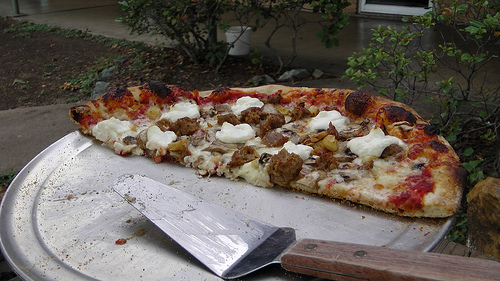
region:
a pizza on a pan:
[79, 52, 486, 259]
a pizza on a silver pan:
[29, 34, 496, 254]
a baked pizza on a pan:
[73, 57, 485, 275]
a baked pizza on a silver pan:
[14, 51, 483, 278]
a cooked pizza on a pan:
[44, 48, 413, 278]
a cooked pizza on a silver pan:
[87, 40, 446, 279]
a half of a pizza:
[54, 31, 406, 275]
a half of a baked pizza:
[55, 43, 389, 275]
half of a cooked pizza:
[73, 46, 462, 278]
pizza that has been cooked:
[75, 43, 499, 243]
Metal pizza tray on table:
[44, 147, 151, 274]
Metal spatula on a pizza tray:
[119, 151, 281, 263]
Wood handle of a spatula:
[293, 221, 462, 276]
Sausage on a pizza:
[269, 132, 309, 184]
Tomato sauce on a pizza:
[402, 148, 429, 229]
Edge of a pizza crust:
[423, 186, 447, 218]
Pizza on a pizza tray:
[87, 67, 464, 227]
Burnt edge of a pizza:
[341, 86, 421, 151]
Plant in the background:
[344, 43, 451, 103]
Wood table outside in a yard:
[7, 106, 47, 141]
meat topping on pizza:
[264, 149, 306, 186]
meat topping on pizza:
[257, 112, 284, 139]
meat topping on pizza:
[223, 146, 258, 171]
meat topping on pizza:
[260, 130, 289, 148]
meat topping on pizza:
[173, 117, 202, 139]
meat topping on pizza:
[166, 134, 190, 157]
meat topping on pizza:
[217, 108, 236, 127]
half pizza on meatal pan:
[0, 81, 459, 279]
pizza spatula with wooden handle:
[114, 173, 497, 279]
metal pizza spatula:
[112, 172, 497, 278]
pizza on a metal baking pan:
[81, 80, 370, 181]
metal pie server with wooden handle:
[96, 158, 322, 268]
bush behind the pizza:
[359, 18, 476, 145]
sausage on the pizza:
[266, 145, 302, 180]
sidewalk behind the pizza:
[14, 103, 69, 163]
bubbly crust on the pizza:
[63, 79, 183, 116]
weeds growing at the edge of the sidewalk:
[26, 12, 96, 47]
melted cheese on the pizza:
[357, 140, 381, 155]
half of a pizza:
[90, 45, 455, 230]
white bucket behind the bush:
[222, 26, 251, 60]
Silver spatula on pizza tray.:
[126, 172, 244, 278]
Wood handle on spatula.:
[292, 218, 418, 278]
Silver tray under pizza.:
[58, 115, 385, 265]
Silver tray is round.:
[41, 130, 401, 277]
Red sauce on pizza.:
[398, 165, 431, 220]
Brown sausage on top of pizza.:
[265, 145, 306, 173]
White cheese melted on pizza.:
[356, 130, 387, 156]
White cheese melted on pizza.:
[221, 123, 263, 152]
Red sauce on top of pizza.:
[183, 89, 244, 103]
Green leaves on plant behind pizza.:
[377, 35, 429, 67]